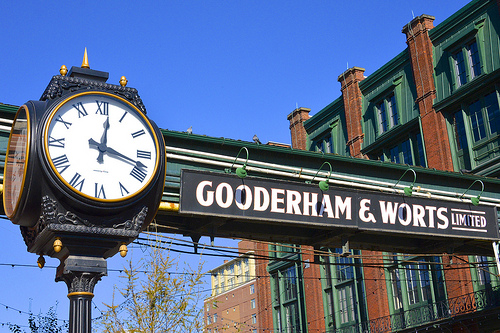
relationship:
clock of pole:
[43, 91, 163, 210] [59, 253, 109, 332]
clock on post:
[43, 91, 163, 210] [59, 253, 109, 332]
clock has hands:
[43, 91, 163, 210] [89, 117, 149, 169]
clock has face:
[43, 91, 163, 210] [41, 92, 158, 201]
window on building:
[214, 272, 220, 286] [205, 239, 275, 332]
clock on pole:
[43, 91, 163, 210] [59, 253, 109, 332]